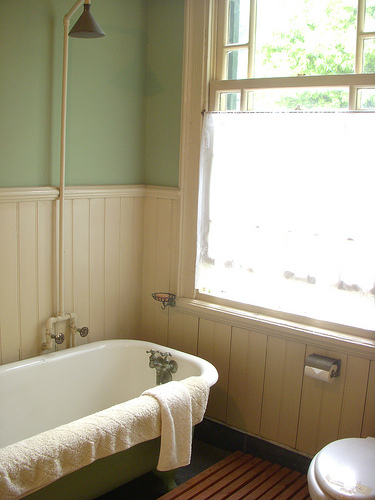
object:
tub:
[1, 333, 242, 499]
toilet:
[301, 406, 374, 499]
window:
[191, 0, 374, 332]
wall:
[90, 62, 154, 145]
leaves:
[308, 53, 321, 70]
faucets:
[146, 347, 160, 370]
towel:
[142, 373, 194, 471]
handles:
[76, 323, 90, 341]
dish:
[148, 286, 179, 311]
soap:
[157, 290, 170, 301]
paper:
[301, 366, 335, 386]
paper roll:
[301, 343, 337, 388]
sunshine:
[258, 73, 370, 165]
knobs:
[52, 327, 66, 345]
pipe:
[54, 30, 71, 327]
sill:
[179, 285, 224, 333]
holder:
[304, 353, 344, 379]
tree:
[288, 31, 337, 84]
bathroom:
[12, 9, 374, 499]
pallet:
[201, 456, 300, 497]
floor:
[141, 448, 355, 499]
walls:
[142, 92, 180, 140]